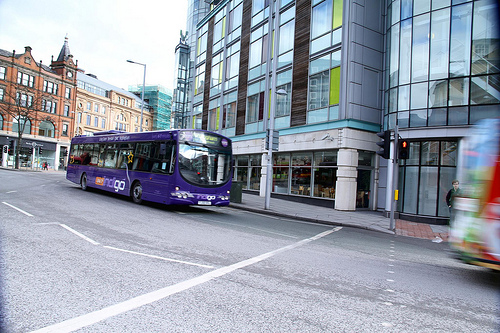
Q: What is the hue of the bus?
A: Purple.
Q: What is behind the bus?
A: Building.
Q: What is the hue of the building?
A: Red brick.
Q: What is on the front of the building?
A: Windows.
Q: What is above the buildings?
A: Bright sky.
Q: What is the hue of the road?
A: Gray.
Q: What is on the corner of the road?
A: Streetlight.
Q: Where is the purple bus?
A: Near the curb.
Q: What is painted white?
A: Marking on the street.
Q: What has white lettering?
A: A purple bus.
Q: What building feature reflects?
A: Glass windows.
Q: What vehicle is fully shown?
A: A purple bus.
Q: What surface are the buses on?
A: A paved road.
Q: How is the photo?
A: Blurry.